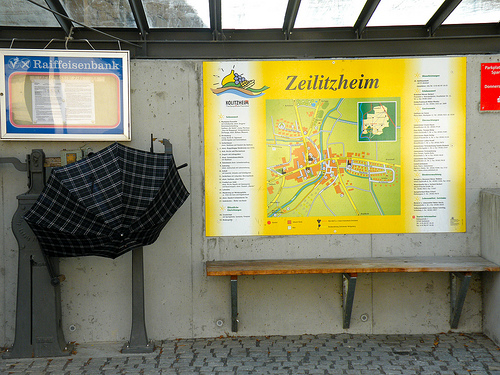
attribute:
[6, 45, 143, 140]
glass case — protective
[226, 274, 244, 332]
bracket — metal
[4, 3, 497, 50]
roof — glass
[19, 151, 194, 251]
umbrella — black, grey, plaid, hanging, upside down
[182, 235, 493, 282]
bench — wood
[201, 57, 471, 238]
poster — bright yellow, white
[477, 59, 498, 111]
sign — red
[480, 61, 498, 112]
red sign — white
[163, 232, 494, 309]
bench — brown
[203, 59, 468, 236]
sign — is yellow, is white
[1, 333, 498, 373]
ground — grey, cobbled, dark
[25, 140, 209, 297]
umberella — upside down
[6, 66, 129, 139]
sign — blue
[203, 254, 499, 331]
bench — wooden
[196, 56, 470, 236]
map — yellow, large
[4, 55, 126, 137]
poster — information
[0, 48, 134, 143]
box — glass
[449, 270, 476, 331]
bar — green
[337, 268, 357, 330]
bar — green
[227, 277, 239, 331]
bar — green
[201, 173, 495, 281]
bench — fixed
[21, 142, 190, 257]
umbrella — plaid, dark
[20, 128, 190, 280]
umbrella — open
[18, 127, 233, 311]
umbrella — black, open, white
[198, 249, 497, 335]
wooden bench — empty